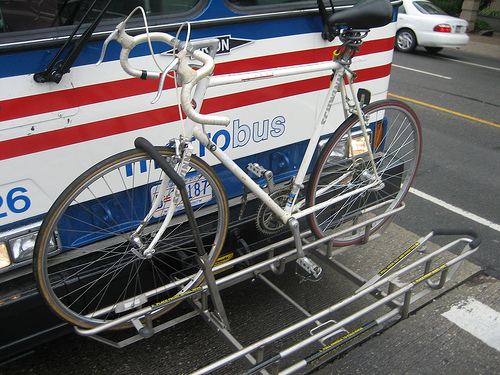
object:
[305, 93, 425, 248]
tire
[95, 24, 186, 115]
breaks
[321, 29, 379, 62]
chain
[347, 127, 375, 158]
light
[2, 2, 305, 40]
windshield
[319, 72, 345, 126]
schwinn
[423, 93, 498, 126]
line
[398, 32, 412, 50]
hubcap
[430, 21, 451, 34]
tail lights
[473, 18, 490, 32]
grass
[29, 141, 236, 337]
front tire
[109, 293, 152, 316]
reflector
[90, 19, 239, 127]
handle bars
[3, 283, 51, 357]
bumper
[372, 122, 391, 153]
reflector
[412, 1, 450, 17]
back windshield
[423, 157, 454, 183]
crack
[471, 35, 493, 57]
sidewalk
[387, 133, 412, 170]
spokes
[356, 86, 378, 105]
reflector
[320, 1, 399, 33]
seat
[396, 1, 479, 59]
car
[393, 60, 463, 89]
line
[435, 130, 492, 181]
road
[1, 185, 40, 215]
number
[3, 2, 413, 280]
bus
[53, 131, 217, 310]
wheel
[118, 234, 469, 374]
bike rack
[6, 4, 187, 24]
window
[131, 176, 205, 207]
license plate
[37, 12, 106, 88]
windshield wiper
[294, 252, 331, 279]
pedal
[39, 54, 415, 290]
bicycle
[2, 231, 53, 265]
headlights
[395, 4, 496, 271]
background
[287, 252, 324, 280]
pedals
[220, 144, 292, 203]
tube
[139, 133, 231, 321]
harness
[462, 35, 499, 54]
curb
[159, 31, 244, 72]
manufacturer